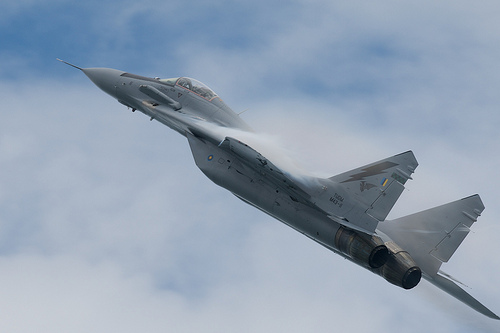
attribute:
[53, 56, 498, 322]
jet — fighter, gray, military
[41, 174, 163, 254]
clouds — white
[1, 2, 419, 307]
sky — blue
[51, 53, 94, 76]
nose — pointed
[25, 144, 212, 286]
clouds — wispy 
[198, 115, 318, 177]
smoke — coming from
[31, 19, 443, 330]
sky — blue, whispy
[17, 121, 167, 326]
clouds — white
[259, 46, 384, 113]
clouds — white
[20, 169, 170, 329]
sky — blue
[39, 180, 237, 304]
clouds — white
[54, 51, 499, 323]
plane — upward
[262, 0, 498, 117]
cloud — white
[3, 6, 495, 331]
clouds — white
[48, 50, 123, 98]
nose — pointed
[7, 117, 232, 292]
sky — blue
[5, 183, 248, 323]
sky — blue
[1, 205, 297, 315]
sky — blue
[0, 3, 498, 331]
sky — blue, cloudy